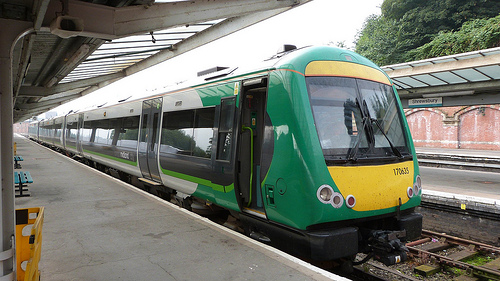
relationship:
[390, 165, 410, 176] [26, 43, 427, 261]
numbers on train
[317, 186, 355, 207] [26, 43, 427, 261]
lights on train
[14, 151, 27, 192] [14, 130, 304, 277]
benches by train stop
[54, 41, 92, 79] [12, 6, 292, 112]
light on ceiling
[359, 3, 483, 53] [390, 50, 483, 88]
trees over roof top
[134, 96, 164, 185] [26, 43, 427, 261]
doors on side of train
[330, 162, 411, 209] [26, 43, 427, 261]
section on front of train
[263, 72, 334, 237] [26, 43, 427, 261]
section on side of train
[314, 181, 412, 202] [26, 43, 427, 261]
lights on front of train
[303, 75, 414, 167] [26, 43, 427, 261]
windshield on front of train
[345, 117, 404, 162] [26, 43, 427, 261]
wipers on front of train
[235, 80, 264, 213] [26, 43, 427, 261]
door on train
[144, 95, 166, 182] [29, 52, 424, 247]
doors in middle of train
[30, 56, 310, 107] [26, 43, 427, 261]
top section of train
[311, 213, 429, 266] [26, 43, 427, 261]
front of train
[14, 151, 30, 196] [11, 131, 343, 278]
benches on platform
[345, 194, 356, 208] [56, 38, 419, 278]
lights on front of train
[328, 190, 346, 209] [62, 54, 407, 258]
headlight on front of train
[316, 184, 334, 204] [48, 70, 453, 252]
lights on front of train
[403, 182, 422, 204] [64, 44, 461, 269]
headlight on front of train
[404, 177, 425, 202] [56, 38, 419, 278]
headlight on front of train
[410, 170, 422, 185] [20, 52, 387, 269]
headlight on front of train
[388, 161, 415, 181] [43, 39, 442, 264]
number on front of train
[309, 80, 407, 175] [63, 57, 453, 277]
windshield on front of train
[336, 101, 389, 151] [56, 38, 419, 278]
wipers on front of train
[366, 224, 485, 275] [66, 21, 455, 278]
tracks under train